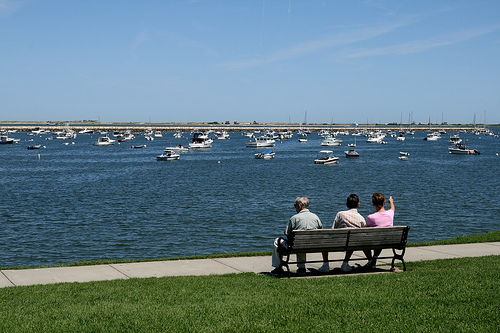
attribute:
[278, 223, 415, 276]
bench — wood, wooden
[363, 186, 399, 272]
woman — pointing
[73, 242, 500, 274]
sidewalk — cement, grey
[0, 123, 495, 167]
boats — recreational, sail, many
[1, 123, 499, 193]
ocean — blue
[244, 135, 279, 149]
boat — white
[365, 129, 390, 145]
boat — white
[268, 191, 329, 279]
man — old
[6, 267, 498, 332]
grass — green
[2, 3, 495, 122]
sky — blue, thin, white, cloudless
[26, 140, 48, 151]
boat — small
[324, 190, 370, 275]
person — in middle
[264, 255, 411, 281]
shoes — white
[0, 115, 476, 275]
marina — black, white, floating